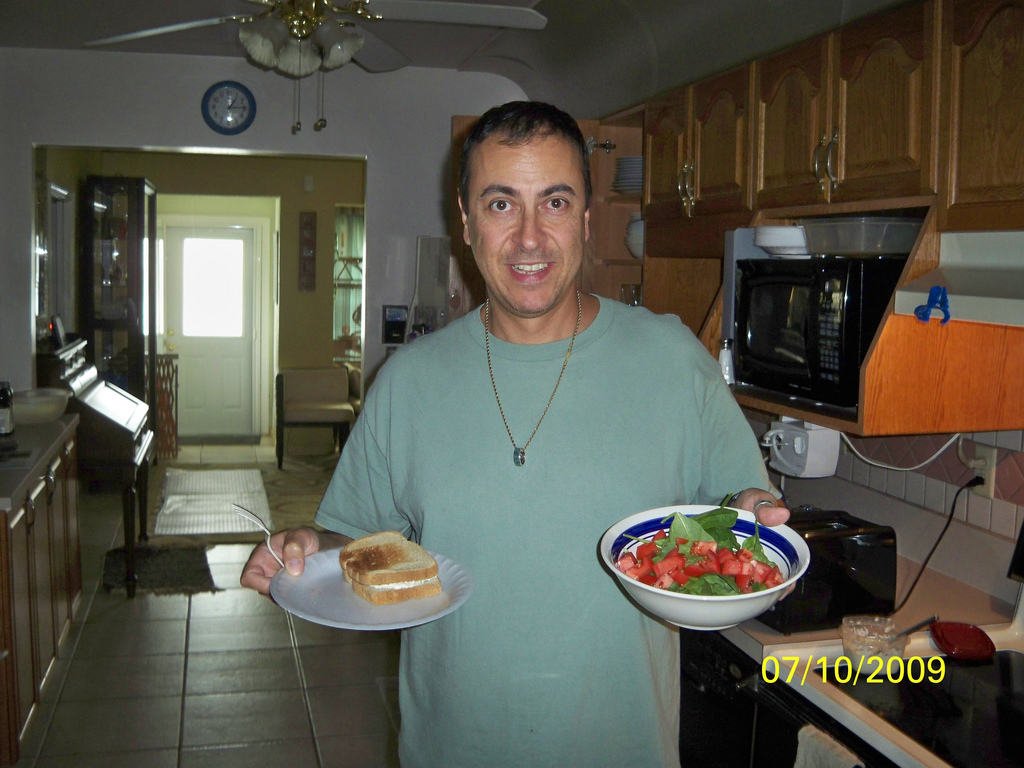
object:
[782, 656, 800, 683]
number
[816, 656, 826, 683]
number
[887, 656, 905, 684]
number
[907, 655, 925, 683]
number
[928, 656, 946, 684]
number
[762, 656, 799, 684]
numbers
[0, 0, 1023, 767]
kitchen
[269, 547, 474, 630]
plate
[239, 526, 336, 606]
hand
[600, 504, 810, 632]
bowl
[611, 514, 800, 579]
stripe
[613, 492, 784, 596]
salad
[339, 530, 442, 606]
sandwich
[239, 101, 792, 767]
man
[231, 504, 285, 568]
utensil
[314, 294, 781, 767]
t-shirt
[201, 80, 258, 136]
clock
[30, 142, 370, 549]
doorway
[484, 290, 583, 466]
necklace